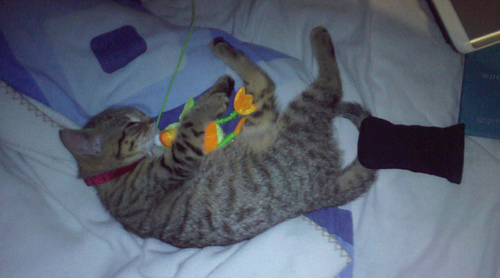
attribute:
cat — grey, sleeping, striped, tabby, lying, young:
[60, 26, 380, 247]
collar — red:
[83, 155, 147, 186]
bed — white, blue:
[0, 0, 499, 277]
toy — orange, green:
[156, 1, 258, 157]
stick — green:
[153, 1, 196, 128]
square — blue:
[90, 24, 147, 73]